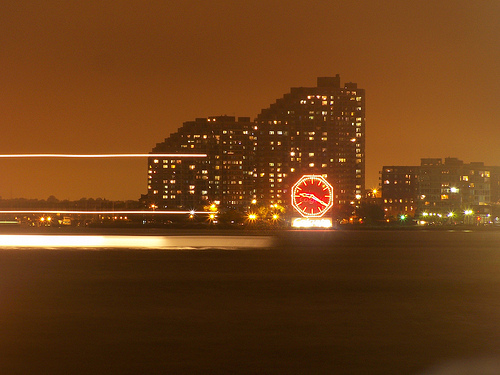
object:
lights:
[289, 174, 335, 228]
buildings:
[138, 113, 255, 214]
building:
[253, 75, 385, 222]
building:
[377, 156, 498, 229]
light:
[384, 180, 390, 184]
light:
[421, 195, 427, 199]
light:
[441, 194, 449, 199]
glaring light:
[450, 187, 457, 193]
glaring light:
[400, 215, 406, 220]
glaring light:
[423, 211, 428, 216]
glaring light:
[464, 209, 473, 215]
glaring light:
[448, 212, 454, 218]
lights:
[38, 215, 53, 223]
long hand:
[312, 194, 329, 207]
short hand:
[299, 193, 312, 199]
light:
[243, 210, 259, 224]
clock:
[289, 175, 335, 219]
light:
[290, 217, 332, 228]